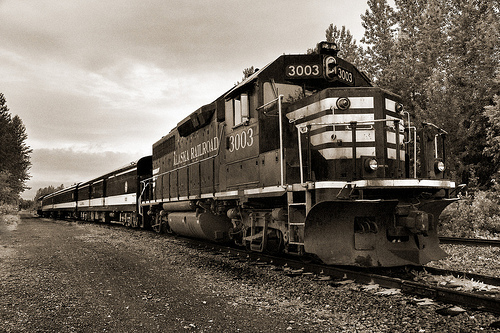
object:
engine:
[145, 38, 470, 270]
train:
[32, 39, 457, 276]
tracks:
[359, 264, 499, 329]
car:
[88, 177, 105, 215]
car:
[32, 179, 78, 221]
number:
[246, 124, 254, 147]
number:
[311, 61, 321, 78]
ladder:
[281, 187, 313, 248]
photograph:
[3, 2, 499, 333]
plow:
[301, 195, 463, 271]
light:
[359, 155, 381, 174]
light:
[434, 159, 452, 176]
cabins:
[105, 162, 143, 226]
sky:
[2, 0, 238, 74]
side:
[146, 53, 285, 204]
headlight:
[326, 65, 341, 81]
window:
[231, 93, 255, 128]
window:
[260, 78, 308, 114]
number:
[348, 72, 356, 82]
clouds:
[1, 69, 106, 87]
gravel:
[343, 292, 352, 298]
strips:
[281, 92, 377, 122]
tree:
[1, 95, 31, 228]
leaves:
[4, 119, 11, 124]